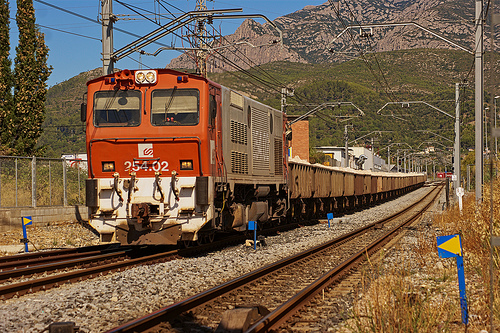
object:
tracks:
[0, 244, 181, 296]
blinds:
[94, 91, 139, 112]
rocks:
[109, 273, 181, 299]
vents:
[231, 150, 248, 175]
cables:
[0, 0, 426, 164]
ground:
[0, 224, 499, 332]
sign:
[433, 226, 471, 330]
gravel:
[0, 302, 100, 333]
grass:
[39, 48, 500, 160]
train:
[68, 58, 444, 246]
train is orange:
[77, 60, 329, 266]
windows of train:
[93, 89, 142, 126]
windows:
[150, 89, 197, 126]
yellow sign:
[425, 222, 481, 331]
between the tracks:
[420, 188, 426, 195]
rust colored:
[114, 218, 183, 246]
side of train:
[200, 80, 285, 246]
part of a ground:
[391, 200, 435, 328]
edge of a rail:
[429, 181, 445, 192]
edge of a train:
[358, 170, 427, 194]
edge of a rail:
[0, 248, 80, 302]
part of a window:
[167, 90, 195, 125]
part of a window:
[154, 91, 192, 122]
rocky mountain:
[189, 6, 374, 79]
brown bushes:
[333, 179, 500, 333]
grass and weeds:
[461, 153, 500, 188]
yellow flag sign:
[433, 225, 484, 330]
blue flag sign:
[248, 221, 257, 250]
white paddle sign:
[454, 183, 470, 223]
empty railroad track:
[148, 254, 363, 332]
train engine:
[72, 61, 294, 257]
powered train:
[75, 66, 439, 259]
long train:
[79, 68, 434, 256]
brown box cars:
[286, 161, 427, 226]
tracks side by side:
[262, 103, 445, 240]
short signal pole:
[327, 213, 334, 228]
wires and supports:
[326, 0, 422, 147]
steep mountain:
[42, 52, 109, 151]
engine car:
[79, 68, 286, 249]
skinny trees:
[0, 3, 60, 160]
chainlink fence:
[0, 155, 87, 208]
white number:
[124, 161, 170, 172]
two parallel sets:
[0, 187, 436, 333]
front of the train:
[80, 69, 215, 246]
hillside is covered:
[46, 49, 500, 170]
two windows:
[93, 88, 201, 127]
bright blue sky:
[0, 0, 328, 96]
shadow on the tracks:
[160, 305, 216, 333]